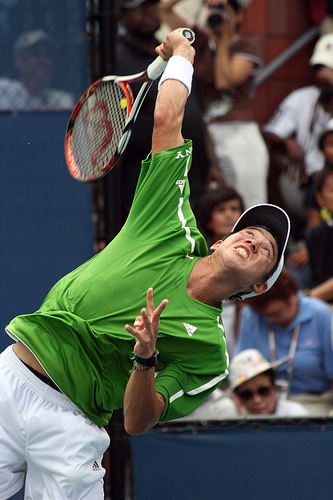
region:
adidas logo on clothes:
[177, 321, 195, 346]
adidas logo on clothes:
[87, 460, 104, 473]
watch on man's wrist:
[134, 344, 162, 371]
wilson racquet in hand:
[64, 67, 158, 193]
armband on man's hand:
[155, 56, 193, 96]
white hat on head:
[241, 195, 287, 245]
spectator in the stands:
[220, 340, 294, 411]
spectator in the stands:
[251, 279, 332, 371]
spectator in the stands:
[305, 167, 329, 287]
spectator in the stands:
[208, 186, 245, 225]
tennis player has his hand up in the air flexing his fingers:
[106, 282, 188, 367]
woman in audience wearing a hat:
[220, 336, 294, 414]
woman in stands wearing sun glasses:
[234, 378, 276, 404]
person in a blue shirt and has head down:
[237, 228, 332, 377]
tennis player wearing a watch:
[124, 352, 171, 370]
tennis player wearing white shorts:
[0, 348, 126, 498]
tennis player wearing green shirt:
[8, 141, 208, 411]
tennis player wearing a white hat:
[184, 201, 290, 303]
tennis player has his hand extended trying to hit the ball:
[35, 14, 329, 486]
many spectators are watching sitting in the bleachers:
[1, 0, 331, 464]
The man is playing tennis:
[58, 16, 239, 215]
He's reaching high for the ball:
[60, 15, 260, 244]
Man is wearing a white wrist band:
[151, 48, 204, 96]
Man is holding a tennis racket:
[32, 16, 230, 181]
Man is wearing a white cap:
[221, 194, 302, 319]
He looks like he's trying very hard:
[198, 178, 311, 328]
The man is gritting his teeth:
[213, 226, 265, 285]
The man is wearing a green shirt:
[41, 173, 251, 430]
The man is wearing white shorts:
[2, 332, 139, 498]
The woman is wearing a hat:
[207, 332, 310, 419]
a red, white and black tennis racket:
[62, 26, 192, 179]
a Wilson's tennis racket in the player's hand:
[63, 25, 194, 183]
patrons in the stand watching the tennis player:
[114, 0, 331, 417]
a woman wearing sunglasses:
[238, 384, 271, 404]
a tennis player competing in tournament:
[0, 26, 292, 499]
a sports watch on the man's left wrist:
[129, 351, 160, 369]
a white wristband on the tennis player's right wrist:
[156, 54, 193, 94]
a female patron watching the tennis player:
[227, 347, 310, 415]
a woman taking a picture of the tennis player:
[205, 1, 270, 180]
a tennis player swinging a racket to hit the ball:
[1, 26, 292, 498]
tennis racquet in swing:
[23, 11, 225, 187]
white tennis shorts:
[2, 341, 114, 499]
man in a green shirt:
[7, 147, 281, 428]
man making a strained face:
[184, 187, 309, 316]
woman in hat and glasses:
[222, 338, 309, 422]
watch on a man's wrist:
[114, 300, 175, 382]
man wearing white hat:
[212, 195, 301, 316]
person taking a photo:
[179, 1, 280, 149]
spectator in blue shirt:
[233, 260, 332, 397]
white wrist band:
[139, 35, 223, 109]